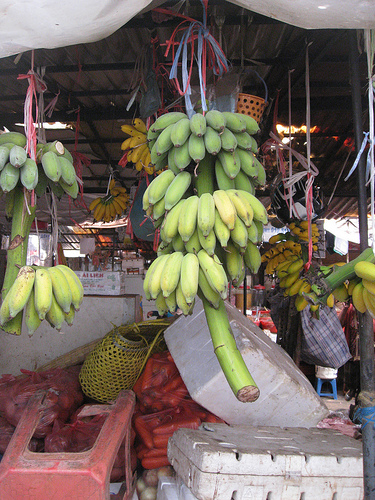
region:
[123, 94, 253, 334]
green bananas on stalk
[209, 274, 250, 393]
long and green stalk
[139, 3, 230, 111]
blue and red ribbon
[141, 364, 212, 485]
produce in red bag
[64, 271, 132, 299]
red and white sign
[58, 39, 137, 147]
black beams on ceiling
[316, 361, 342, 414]
blue and white seat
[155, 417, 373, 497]
grey crate under green stem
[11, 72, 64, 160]
red and white string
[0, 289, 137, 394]
grey wall under white and red sign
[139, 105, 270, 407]
stalk of green bananas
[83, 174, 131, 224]
bunch of yellow bananas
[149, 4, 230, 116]
red and blue ribbon hanging from ceiling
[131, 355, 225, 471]
plastic bag full of carrots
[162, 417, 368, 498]
white styrofoam container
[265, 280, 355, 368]
plaid plastic bag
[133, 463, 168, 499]
pile of yellow onions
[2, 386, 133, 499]
red step stool turned on its side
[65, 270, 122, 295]
white menu on wall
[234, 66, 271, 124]
brown basket with blue handle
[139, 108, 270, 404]
a bunch of bananas on a branch.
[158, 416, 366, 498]
A large container.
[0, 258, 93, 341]
Bananas hanging from a branch.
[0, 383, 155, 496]
a red plastic stool.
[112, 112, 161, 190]
a bunch of yellow bananas.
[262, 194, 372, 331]
A bunch of bananas in a store.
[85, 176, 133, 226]
Bananas hanging from a ceiling.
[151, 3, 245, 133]
streamers hanging from a ceiling.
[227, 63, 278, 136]
a basket hanging from a ceiling.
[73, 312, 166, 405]
A rolled up net.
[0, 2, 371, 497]
Food at a market place.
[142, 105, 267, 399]
A bunch of green bananas.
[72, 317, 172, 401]
The bag is yellow.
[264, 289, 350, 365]
The bag is plaid.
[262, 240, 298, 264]
A bunch of yellow bananas.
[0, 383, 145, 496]
A red stool on its side.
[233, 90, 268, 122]
The basket is orange.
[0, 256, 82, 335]
A Small bunch of banans.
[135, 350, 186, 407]
Carrots in a plastic bag.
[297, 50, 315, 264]
A string hanging down.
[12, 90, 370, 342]
Bananas hanging from the ceiling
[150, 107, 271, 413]
These bananas are still on the tree branch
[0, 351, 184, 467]
Bags of carrots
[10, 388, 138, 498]
A red stool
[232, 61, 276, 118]
A basket with a blue handle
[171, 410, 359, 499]
Styrofoam container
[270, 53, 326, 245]
String hanging from the ceiling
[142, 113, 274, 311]
These bananas are not ripe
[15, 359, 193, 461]
The carrots are in bags made of plastic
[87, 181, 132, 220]
This group of bananas is yellow and ripe